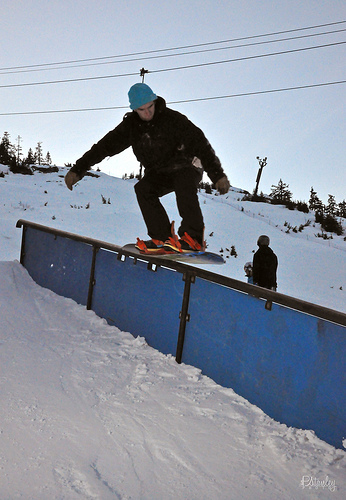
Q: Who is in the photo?
A: A snowboarder.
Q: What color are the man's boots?
A: Orange.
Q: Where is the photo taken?
A: A mountain.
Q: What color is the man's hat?
A: Light blue.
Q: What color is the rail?
A: Black.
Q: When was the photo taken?
A: During the day.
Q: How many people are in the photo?
A: Two.